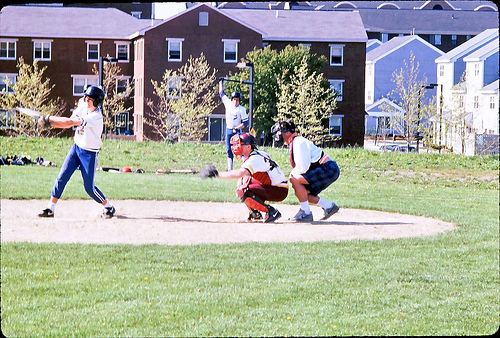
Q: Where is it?
A: This is at the field.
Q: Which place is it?
A: It is a field.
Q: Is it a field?
A: Yes, it is a field.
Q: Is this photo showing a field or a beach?
A: It is showing a field.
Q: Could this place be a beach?
A: No, it is a field.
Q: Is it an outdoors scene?
A: Yes, it is outdoors.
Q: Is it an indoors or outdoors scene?
A: It is outdoors.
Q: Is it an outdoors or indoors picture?
A: It is outdoors.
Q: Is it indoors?
A: No, it is outdoors.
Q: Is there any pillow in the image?
A: No, there are no pillows.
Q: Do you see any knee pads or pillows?
A: No, there are no pillows or knee pads.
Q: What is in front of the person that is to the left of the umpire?
A: The home plate is in front of the catcher.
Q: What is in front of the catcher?
A: The home plate is in front of the catcher.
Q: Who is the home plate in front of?
A: The home plate is in front of the catcher.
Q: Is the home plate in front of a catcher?
A: Yes, the home plate is in front of a catcher.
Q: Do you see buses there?
A: No, there are no buses.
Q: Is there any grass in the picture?
A: Yes, there is grass.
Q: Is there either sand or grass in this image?
A: Yes, there is grass.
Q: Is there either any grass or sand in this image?
A: Yes, there is grass.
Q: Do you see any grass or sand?
A: Yes, there is grass.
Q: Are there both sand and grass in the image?
A: Yes, there are both grass and sand.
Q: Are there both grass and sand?
A: Yes, there are both grass and sand.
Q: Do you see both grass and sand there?
A: Yes, there are both grass and sand.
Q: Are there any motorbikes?
A: No, there are no motorbikes.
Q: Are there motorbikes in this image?
A: No, there are no motorbikes.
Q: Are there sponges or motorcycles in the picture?
A: No, there are no motorcycles or sponges.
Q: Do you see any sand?
A: Yes, there is sand.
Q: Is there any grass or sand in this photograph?
A: Yes, there is sand.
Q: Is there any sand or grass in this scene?
A: Yes, there is sand.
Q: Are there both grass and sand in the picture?
A: Yes, there are both sand and grass.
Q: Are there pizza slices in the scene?
A: No, there are no pizza slices.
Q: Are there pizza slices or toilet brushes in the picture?
A: No, there are no pizza slices or toilet brushes.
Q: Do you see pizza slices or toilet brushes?
A: No, there are no pizza slices or toilet brushes.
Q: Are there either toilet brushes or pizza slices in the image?
A: No, there are no pizza slices or toilet brushes.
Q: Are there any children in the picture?
A: Yes, there is a child.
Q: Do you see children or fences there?
A: Yes, there is a child.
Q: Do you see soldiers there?
A: No, there are no soldiers.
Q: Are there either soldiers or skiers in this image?
A: No, there are no soldiers or skiers.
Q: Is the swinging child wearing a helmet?
A: Yes, the kid is wearing a helmet.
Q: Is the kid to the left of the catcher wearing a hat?
A: No, the kid is wearing a helmet.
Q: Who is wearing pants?
A: The child is wearing pants.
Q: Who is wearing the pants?
A: The child is wearing pants.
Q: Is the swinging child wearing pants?
A: Yes, the child is wearing pants.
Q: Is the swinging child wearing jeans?
A: No, the kid is wearing pants.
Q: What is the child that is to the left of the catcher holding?
A: The kid is holding the bat.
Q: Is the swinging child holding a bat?
A: Yes, the kid is holding a bat.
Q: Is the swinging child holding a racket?
A: No, the child is holding a bat.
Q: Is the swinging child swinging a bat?
A: Yes, the kid is swinging a bat.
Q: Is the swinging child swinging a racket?
A: No, the child is swinging a bat.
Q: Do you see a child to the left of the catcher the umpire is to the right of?
A: Yes, there is a child to the left of the catcher.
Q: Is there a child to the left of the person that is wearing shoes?
A: Yes, there is a child to the left of the catcher.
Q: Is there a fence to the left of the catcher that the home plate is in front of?
A: No, there is a child to the left of the catcher.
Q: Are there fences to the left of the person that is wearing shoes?
A: No, there is a child to the left of the catcher.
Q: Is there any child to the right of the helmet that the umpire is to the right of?
A: No, the child is to the left of the helmet.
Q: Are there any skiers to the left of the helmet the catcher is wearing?
A: No, there is a child to the left of the helmet.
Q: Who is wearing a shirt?
A: The child is wearing a shirt.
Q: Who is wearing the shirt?
A: The child is wearing a shirt.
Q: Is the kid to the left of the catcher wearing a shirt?
A: Yes, the kid is wearing a shirt.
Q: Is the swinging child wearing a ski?
A: No, the child is wearing a shirt.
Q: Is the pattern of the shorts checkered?
A: Yes, the shorts are checkered.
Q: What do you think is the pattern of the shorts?
A: The shorts are checkered.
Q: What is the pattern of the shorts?
A: The shorts are checkered.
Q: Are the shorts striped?
A: No, the shorts are checkered.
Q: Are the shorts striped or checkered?
A: The shorts are checkered.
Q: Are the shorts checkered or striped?
A: The shorts are checkered.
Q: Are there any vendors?
A: No, there are no vendors.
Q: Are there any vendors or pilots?
A: No, there are no vendors or pilots.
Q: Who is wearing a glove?
A: The catcher is wearing a glove.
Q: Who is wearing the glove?
A: The catcher is wearing a glove.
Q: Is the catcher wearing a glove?
A: Yes, the catcher is wearing a glove.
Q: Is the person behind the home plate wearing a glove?
A: Yes, the catcher is wearing a glove.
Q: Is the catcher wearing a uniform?
A: No, the catcher is wearing a glove.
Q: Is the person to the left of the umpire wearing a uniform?
A: No, the catcher is wearing a glove.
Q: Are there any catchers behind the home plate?
A: Yes, there is a catcher behind the home plate.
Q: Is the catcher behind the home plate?
A: Yes, the catcher is behind the home plate.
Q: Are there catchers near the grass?
A: Yes, there is a catcher near the grass.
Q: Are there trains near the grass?
A: No, there is a catcher near the grass.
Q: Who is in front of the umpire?
A: The catcher is in front of the umpire.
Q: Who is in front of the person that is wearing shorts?
A: The catcher is in front of the umpire.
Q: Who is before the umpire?
A: The catcher is in front of the umpire.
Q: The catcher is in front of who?
A: The catcher is in front of the umpire.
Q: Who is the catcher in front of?
A: The catcher is in front of the umpire.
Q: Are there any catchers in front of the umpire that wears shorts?
A: Yes, there is a catcher in front of the umpire.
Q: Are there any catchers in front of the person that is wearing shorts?
A: Yes, there is a catcher in front of the umpire.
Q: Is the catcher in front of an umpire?
A: Yes, the catcher is in front of an umpire.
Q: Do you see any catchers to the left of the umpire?
A: Yes, there is a catcher to the left of the umpire.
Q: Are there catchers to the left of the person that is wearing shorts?
A: Yes, there is a catcher to the left of the umpire.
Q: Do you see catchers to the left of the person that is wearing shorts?
A: Yes, there is a catcher to the left of the umpire.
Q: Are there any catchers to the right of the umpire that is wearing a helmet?
A: No, the catcher is to the left of the umpire.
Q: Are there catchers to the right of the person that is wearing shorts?
A: No, the catcher is to the left of the umpire.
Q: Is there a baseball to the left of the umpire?
A: No, there is a catcher to the left of the umpire.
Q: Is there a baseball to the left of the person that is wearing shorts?
A: No, there is a catcher to the left of the umpire.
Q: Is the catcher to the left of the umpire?
A: Yes, the catcher is to the left of the umpire.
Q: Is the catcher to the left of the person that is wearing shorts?
A: Yes, the catcher is to the left of the umpire.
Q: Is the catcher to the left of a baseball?
A: No, the catcher is to the left of the umpire.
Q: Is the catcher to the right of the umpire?
A: No, the catcher is to the left of the umpire.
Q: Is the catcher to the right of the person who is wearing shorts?
A: No, the catcher is to the left of the umpire.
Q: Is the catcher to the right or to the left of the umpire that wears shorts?
A: The catcher is to the left of the umpire.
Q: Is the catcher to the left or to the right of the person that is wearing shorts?
A: The catcher is to the left of the umpire.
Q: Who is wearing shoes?
A: The catcher is wearing shoes.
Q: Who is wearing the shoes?
A: The catcher is wearing shoes.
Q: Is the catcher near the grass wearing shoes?
A: Yes, the catcher is wearing shoes.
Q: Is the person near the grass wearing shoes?
A: Yes, the catcher is wearing shoes.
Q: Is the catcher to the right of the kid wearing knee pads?
A: No, the catcher is wearing shoes.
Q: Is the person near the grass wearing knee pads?
A: No, the catcher is wearing shoes.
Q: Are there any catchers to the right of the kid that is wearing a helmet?
A: Yes, there is a catcher to the right of the kid.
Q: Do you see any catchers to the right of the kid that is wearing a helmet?
A: Yes, there is a catcher to the right of the kid.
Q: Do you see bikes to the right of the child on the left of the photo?
A: No, there is a catcher to the right of the child.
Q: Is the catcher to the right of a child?
A: Yes, the catcher is to the right of a child.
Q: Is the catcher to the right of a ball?
A: No, the catcher is to the right of a child.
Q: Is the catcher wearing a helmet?
A: Yes, the catcher is wearing a helmet.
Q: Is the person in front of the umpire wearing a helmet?
A: Yes, the catcher is wearing a helmet.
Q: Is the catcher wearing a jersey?
A: No, the catcher is wearing a helmet.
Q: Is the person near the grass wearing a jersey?
A: No, the catcher is wearing a helmet.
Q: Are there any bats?
A: Yes, there is a bat.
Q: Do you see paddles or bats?
A: Yes, there is a bat.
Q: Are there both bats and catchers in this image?
A: Yes, there are both a bat and a catcher.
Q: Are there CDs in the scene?
A: No, there are no cds.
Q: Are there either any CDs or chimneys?
A: No, there are no CDs or chimneys.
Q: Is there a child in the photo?
A: Yes, there is a child.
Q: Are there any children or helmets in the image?
A: Yes, there is a child.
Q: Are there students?
A: No, there are no students.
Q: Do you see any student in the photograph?
A: No, there are no students.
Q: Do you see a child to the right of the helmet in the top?
A: Yes, there is a child to the right of the helmet.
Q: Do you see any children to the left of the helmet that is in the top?
A: No, the child is to the right of the helmet.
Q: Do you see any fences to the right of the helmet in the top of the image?
A: No, there is a child to the right of the helmet.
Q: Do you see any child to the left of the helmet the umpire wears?
A: Yes, there is a child to the left of the helmet.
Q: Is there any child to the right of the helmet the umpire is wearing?
A: No, the child is to the left of the helmet.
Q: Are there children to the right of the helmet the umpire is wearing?
A: No, the child is to the left of the helmet.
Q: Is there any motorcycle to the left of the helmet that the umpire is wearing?
A: No, there is a child to the left of the helmet.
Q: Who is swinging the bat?
A: The kid is swinging the bat.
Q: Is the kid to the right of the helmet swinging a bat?
A: Yes, the kid is swinging a bat.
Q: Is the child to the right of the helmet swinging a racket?
A: No, the kid is swinging a bat.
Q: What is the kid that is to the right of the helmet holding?
A: The kid is holding the bat.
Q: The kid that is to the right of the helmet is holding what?
A: The kid is holding the bat.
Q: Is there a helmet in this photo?
A: Yes, there is a helmet.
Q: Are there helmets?
A: Yes, there is a helmet.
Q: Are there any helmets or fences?
A: Yes, there is a helmet.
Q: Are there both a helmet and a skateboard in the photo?
A: No, there is a helmet but no skateboards.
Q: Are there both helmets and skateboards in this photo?
A: No, there is a helmet but no skateboards.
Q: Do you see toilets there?
A: No, there are no toilets.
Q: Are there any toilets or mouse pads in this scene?
A: No, there are no toilets or mouse pads.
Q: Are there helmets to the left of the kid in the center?
A: Yes, there is a helmet to the left of the child.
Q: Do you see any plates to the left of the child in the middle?
A: No, there is a helmet to the left of the kid.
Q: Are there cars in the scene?
A: No, there are no cars.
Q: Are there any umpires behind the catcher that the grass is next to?
A: Yes, there is an umpire behind the catcher.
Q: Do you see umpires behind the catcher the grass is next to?
A: Yes, there is an umpire behind the catcher.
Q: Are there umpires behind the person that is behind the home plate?
A: Yes, there is an umpire behind the catcher.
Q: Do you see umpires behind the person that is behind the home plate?
A: Yes, there is an umpire behind the catcher.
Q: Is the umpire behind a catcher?
A: Yes, the umpire is behind a catcher.